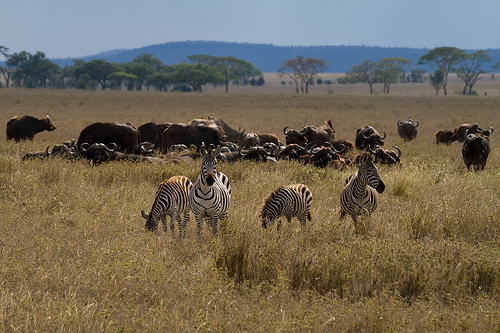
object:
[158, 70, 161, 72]
leaf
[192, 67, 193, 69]
leaf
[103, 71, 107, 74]
leaf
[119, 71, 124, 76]
leaf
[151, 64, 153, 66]
leaf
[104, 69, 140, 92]
tree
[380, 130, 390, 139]
horns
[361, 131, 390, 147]
head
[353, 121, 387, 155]
water buffalo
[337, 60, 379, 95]
tree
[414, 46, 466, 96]
trees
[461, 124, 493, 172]
buffalo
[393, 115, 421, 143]
buffalo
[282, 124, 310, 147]
buffalo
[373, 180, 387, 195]
nose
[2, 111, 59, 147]
animals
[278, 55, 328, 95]
tree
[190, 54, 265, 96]
tree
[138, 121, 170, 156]
buffalo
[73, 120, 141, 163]
buffalo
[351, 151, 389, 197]
zebra head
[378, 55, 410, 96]
trees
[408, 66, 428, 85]
trees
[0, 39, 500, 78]
mountains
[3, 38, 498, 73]
hazy land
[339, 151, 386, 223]
animal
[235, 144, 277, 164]
buffalo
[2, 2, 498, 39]
sky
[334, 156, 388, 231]
animal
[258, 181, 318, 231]
animal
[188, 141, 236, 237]
animal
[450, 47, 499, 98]
trees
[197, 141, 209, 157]
white ear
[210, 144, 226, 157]
white ear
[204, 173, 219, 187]
black nose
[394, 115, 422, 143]
animal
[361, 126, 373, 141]
horns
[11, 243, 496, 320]
grass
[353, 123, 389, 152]
bull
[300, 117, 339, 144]
bull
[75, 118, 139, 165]
bull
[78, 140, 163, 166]
bull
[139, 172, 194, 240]
animals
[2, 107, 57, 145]
bull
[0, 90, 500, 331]
grass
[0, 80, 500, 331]
field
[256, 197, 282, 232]
head